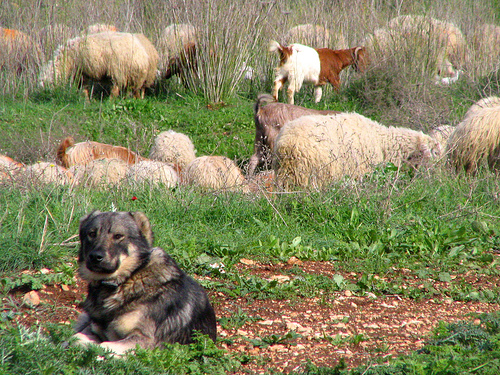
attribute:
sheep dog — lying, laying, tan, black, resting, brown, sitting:
[74, 220, 213, 349]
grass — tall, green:
[385, 236, 472, 252]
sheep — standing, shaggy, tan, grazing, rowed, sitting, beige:
[35, 35, 208, 90]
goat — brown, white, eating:
[253, 51, 368, 96]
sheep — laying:
[145, 123, 248, 201]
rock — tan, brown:
[12, 269, 48, 325]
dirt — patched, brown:
[282, 303, 379, 319]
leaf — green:
[343, 209, 366, 232]